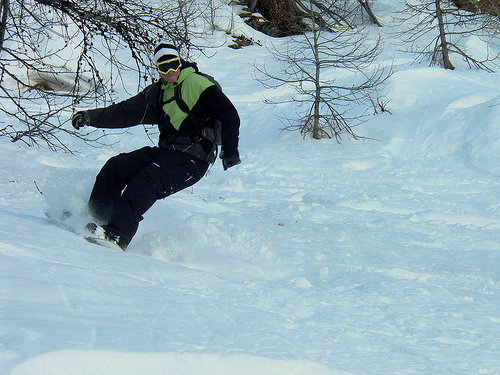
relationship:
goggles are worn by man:
[156, 57, 182, 74] [83, 45, 241, 252]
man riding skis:
[70, 44, 241, 251] [44, 206, 123, 252]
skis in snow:
[44, 206, 123, 252] [4, 144, 495, 373]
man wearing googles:
[70, 44, 241, 251] [156, 54, 186, 77]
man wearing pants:
[70, 44, 241, 251] [86, 142, 208, 249]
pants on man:
[86, 142, 208, 249] [70, 44, 241, 251]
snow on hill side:
[0, 0, 499, 371] [0, 0, 499, 371]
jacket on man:
[83, 60, 243, 164] [51, 39, 242, 251]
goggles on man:
[152, 52, 187, 73] [70, 44, 241, 251]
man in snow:
[70, 44, 241, 251] [0, 0, 499, 371]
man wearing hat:
[70, 44, 241, 251] [152, 41, 181, 64]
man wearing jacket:
[51, 39, 242, 251] [83, 60, 243, 164]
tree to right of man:
[385, 3, 498, 75] [70, 44, 241, 251]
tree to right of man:
[249, 0, 401, 146] [70, 44, 241, 251]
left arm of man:
[205, 81, 242, 168] [51, 39, 242, 251]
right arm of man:
[51, 39, 241, 251] [70, 44, 241, 251]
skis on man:
[10, 201, 121, 253] [70, 44, 241, 251]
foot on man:
[81, 219, 119, 248] [70, 44, 241, 251]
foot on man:
[59, 208, 82, 223] [70, 44, 241, 251]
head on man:
[152, 41, 186, 89] [70, 44, 241, 251]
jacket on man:
[83, 60, 243, 164] [70, 44, 241, 251]